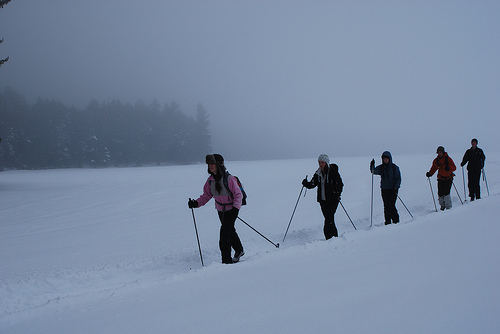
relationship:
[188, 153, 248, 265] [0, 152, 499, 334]
skier walking in snow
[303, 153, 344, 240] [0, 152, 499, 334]
skier walking in snow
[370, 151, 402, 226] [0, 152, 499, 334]
skier walking in snow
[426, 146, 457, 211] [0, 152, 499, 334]
skier walking in snow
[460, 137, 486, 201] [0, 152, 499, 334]
skier walking in snow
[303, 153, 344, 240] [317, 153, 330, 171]
skier has head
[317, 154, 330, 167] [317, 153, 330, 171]
hat on top of head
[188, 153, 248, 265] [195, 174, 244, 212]
skier wearing jacket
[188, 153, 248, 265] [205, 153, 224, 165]
skier wearing hat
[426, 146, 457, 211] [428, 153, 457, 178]
skier wearing jacket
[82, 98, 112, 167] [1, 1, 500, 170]
tree in distance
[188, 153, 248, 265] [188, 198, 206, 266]
skier has pole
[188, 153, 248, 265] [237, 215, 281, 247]
skier has pole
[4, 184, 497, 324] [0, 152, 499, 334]
ditch in middle of snow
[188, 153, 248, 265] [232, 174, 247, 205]
skier carries backpack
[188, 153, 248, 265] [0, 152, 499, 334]
skier hiking through snow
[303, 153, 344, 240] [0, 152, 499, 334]
skier hiking through snow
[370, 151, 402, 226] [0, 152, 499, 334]
skier hiking through snow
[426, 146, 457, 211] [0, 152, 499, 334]
skier hiking through snow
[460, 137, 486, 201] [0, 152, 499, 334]
skier hiking through snow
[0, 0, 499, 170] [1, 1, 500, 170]
fog in distance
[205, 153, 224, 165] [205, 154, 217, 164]
hat has fur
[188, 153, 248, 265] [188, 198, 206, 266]
skier holding pole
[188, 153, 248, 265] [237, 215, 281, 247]
skier holding pole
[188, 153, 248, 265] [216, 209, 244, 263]
skier wearing pants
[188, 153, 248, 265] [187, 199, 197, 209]
skier has hand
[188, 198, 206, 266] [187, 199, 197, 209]
pole being held hand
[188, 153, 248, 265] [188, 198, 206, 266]
skier using pole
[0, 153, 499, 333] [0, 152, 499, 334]
ground covered with snow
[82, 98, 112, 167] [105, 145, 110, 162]
tree with branches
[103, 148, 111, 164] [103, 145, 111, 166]
snow on top of branches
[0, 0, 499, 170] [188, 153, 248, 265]
fog behind skier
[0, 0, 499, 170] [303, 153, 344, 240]
fog behind skier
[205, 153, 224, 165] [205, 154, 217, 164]
hat with fur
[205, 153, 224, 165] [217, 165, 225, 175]
hat has ear flap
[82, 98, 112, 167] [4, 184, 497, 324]
tree next to ditch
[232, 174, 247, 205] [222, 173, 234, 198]
backpack has shoulder strap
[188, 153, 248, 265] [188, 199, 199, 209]
skier wearing glove